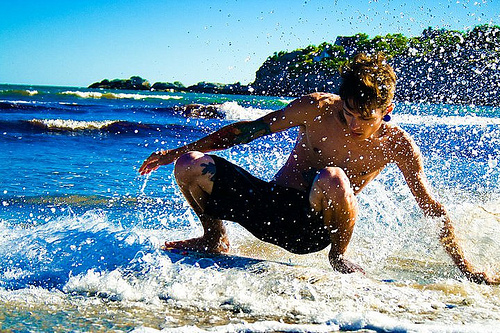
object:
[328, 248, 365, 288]
foot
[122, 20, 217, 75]
sky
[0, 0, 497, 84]
blue sky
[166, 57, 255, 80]
white clouds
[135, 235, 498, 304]
board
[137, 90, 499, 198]
waves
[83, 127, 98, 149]
bright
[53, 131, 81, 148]
color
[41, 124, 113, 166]
water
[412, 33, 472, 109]
trees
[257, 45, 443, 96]
trees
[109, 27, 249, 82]
clouds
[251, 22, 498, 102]
trees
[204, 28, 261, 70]
white clouds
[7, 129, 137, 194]
water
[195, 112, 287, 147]
tattoo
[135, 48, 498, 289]
surfer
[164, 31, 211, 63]
clouds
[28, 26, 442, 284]
photo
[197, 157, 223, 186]
tattoo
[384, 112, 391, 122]
ear lobe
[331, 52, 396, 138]
head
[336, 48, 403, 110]
brown hair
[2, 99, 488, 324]
water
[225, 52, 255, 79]
clouds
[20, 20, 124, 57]
sky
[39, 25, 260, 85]
clouds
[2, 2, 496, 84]
sky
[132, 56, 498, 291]
boy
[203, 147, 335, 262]
shorts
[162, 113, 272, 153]
tattoos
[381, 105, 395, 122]
ear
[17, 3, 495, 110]
sky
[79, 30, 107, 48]
sky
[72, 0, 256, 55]
clouds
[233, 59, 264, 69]
clouds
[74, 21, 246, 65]
sky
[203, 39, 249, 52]
clouds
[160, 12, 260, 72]
clouds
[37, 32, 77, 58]
clouds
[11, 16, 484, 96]
background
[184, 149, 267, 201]
thigh